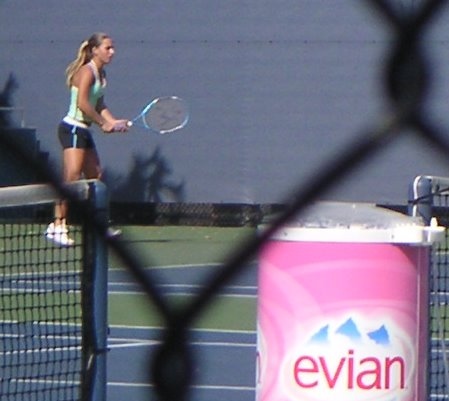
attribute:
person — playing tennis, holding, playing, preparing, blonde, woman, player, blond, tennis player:
[46, 33, 130, 247]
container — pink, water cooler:
[257, 200, 448, 401]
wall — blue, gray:
[1, 3, 448, 207]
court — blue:
[1, 252, 448, 304]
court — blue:
[0, 319, 448, 400]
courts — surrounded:
[1, 250, 449, 400]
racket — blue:
[127, 94, 191, 136]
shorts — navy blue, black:
[57, 121, 96, 151]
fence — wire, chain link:
[1, 2, 448, 400]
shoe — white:
[44, 223, 75, 247]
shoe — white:
[106, 224, 122, 236]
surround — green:
[2, 221, 448, 335]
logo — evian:
[295, 320, 407, 391]